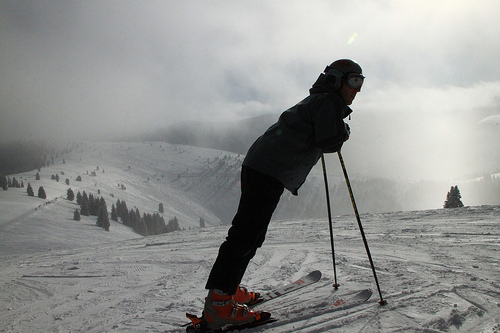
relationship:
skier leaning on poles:
[201, 59, 364, 330] [321, 148, 386, 306]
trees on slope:
[78, 191, 179, 235] [71, 164, 222, 246]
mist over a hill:
[2, 2, 246, 156] [2, 119, 497, 330]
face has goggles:
[342, 70, 364, 107] [345, 75, 364, 92]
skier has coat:
[201, 59, 364, 330] [244, 91, 352, 195]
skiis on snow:
[183, 271, 373, 332] [8, 139, 499, 329]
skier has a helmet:
[201, 59, 364, 330] [325, 59, 362, 81]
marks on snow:
[373, 219, 497, 326] [8, 139, 499, 329]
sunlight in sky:
[278, 2, 473, 45] [3, 0, 499, 141]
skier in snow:
[201, 59, 364, 330] [8, 139, 499, 329]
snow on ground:
[8, 139, 499, 329] [3, 206, 496, 331]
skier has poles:
[201, 59, 364, 330] [321, 148, 386, 306]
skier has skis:
[201, 59, 364, 330] [183, 271, 373, 332]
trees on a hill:
[78, 191, 179, 235] [2, 138, 330, 224]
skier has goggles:
[201, 59, 364, 330] [345, 75, 364, 92]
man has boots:
[201, 59, 364, 330] [201, 287, 271, 330]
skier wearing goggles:
[201, 59, 364, 330] [345, 75, 364, 92]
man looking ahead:
[201, 59, 364, 330] [316, 56, 375, 125]